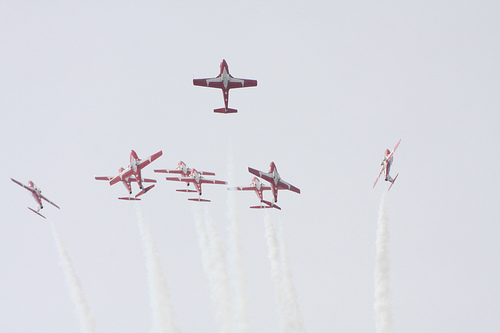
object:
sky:
[1, 1, 500, 330]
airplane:
[246, 159, 305, 205]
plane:
[368, 138, 406, 194]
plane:
[191, 58, 258, 115]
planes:
[365, 140, 403, 191]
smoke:
[372, 186, 394, 331]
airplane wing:
[229, 76, 258, 90]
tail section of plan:
[214, 90, 238, 114]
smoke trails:
[42, 214, 96, 332]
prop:
[219, 58, 228, 64]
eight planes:
[7, 138, 402, 220]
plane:
[11, 177, 63, 221]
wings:
[227, 76, 259, 91]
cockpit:
[388, 154, 394, 165]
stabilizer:
[211, 107, 238, 116]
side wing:
[192, 73, 223, 92]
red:
[197, 80, 200, 83]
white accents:
[205, 69, 244, 90]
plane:
[155, 162, 228, 204]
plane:
[96, 167, 156, 204]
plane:
[227, 176, 285, 211]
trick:
[155, 161, 227, 207]